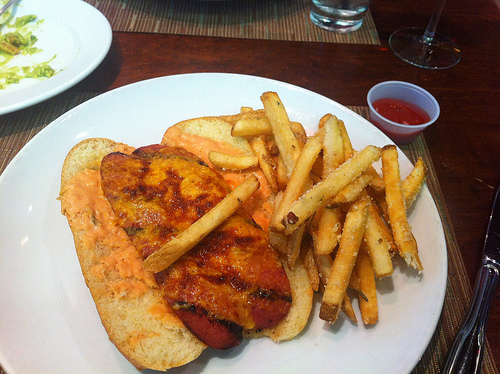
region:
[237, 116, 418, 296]
the fries are brown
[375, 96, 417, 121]
sauce is in the cup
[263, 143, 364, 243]
salt is on the fries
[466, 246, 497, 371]
spoon is on the table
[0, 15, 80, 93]
flowers aare on the plate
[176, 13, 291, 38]
the table mat is grey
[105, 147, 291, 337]
the meat is brown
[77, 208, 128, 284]
mayonesse is on the bread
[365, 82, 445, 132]
the cup is plastic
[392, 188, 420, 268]
the fry is half eaten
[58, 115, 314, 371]
hot dog on bun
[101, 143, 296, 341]
hot dog split open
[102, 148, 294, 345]
grilled hot dog with cheese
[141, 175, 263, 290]
french fried potato on hot dog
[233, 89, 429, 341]
pile of french fried potatoes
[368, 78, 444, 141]
cup of catsup for fries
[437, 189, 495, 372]
stainless steel knife on table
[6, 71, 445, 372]
white plate with hot dog and fries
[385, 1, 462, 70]
stem of glass on table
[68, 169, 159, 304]
sauce on hot dog bun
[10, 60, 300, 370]
Hotdog on a plate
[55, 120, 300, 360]
Hotdog on a white plate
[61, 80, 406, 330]
Hotdog on a plate with fries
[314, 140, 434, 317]
Fries on a white plate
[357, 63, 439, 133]
Red sauce in a small container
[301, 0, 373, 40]
The bottom of a clear glass on a table mat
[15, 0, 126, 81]
Almost empty plate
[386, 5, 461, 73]
The bottom of a wine glass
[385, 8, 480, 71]
The bottom of a wine glass on a wooden table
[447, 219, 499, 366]
Knife handle on a table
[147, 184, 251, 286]
THIS IS A PIECE OF POTATOE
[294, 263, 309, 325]
THIS IS A PIECE OF POTATOE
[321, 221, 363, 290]
THIS IS A PIECE OF POTATOE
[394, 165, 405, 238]
THIS IS A PIECE OF POTATOE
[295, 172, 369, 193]
THIS IS A PIECE OF POTATOE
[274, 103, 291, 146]
THIS IS A PIECE OF POTATOE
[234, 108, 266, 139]
THIS IS A PIECE OF POTATOE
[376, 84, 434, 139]
A BOWL OF SAUCE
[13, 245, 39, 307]
A WHITE PLATE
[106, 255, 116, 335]
THIS IS A PIECE OF POTATOE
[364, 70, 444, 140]
sauce in a plastic cup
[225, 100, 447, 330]
fries on a plate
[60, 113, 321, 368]
a bun on a plate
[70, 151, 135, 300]
cheese on the bun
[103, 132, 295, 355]
meat on the bun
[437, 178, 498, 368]
a knife beside the plate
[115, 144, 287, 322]
cheese on the meat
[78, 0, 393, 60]
a placemat behind the plate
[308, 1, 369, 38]
a glass on the placemat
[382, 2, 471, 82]
stemware on the table